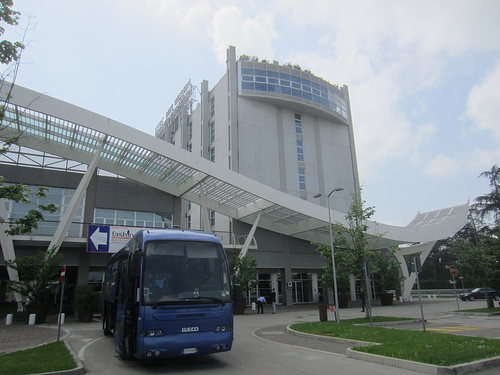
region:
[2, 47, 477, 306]
curved ramp in front of tall white building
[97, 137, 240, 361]
blue bus parked under ramp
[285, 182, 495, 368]
curved grass island with trees and poles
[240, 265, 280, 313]
people standing in front of entryway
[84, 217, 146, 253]
white arrow at end of elevated sign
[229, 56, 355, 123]
curved glass windows extending from building top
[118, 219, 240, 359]
blue bus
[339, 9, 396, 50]
white clouds in blue sky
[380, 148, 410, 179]
white clouds in blue sky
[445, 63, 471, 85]
white clouds in blue sky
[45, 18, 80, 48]
white clouds in blue sky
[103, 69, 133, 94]
white clouds in blue sky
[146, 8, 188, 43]
white clouds in blue sky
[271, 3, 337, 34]
white clouds in blue sky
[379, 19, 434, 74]
white clouds in blue sky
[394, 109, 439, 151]
white clouds in blue sky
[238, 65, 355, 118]
Windows at the top of a building.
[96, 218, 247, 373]
A blue moving bus.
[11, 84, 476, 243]
Railing over the side of a building.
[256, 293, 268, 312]
A person leaning forward.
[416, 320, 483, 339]
A painted street sign.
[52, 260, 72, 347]
A caution sign on a pole.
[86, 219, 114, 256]
A directional arrow.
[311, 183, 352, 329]
Tall light pole in the grass.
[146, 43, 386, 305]
Tall building facing forward.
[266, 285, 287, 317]
Person standing in front of a building.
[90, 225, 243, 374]
the bus is blue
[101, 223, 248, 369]
the bus is blue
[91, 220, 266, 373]
the bus is blue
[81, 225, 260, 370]
the bus is parked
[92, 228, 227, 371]
the bus is parked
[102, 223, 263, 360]
the bus is parked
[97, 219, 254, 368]
the bus is parked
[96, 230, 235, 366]
large long blue bus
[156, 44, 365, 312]
Large tall concrete building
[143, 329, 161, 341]
Small rectangular glass light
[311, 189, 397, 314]
Tall green leafy tree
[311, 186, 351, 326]
Large tall metal pole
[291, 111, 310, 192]
Many rectangular glass windows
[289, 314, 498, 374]
Short green grass lot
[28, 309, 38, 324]
Short white cement pole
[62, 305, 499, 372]
Large cement parking lot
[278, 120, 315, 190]
windows on the building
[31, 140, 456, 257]
the awning is stone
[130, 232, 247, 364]
the bus is blue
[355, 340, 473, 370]
grass in middle section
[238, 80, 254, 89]
glass window on the building